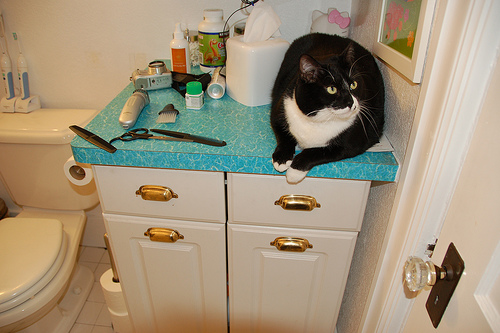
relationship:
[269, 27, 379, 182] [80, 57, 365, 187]
cat on counter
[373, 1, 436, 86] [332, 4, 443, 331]
picture hanging on wall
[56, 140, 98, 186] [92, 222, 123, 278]
toilet paper on holder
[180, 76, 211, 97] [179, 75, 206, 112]
lid on bottle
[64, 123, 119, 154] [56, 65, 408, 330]
comb on corner of cabinet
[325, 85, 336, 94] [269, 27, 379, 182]
eye on cat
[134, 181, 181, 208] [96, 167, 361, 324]
handle on cabinet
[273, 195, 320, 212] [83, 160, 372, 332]
drawer pulls on cabinet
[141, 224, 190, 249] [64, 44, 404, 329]
golden handle on cabinet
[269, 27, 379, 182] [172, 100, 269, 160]
cat sitting on counter top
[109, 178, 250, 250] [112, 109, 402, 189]
drawer under counter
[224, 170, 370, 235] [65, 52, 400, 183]
drawer under counter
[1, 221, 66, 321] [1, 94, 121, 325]
bowl on toilet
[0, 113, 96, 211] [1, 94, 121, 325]
tank on toilet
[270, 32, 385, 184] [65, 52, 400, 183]
cat on counter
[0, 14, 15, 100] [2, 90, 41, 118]
toothbrush sitting upright in stands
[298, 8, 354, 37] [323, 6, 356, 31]
kitty with bow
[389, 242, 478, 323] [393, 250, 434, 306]
door handle with knob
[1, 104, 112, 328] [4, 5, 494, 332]
toilet in bathroom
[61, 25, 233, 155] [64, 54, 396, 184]
items on countertop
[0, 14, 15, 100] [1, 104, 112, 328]
toothbrush on toilet